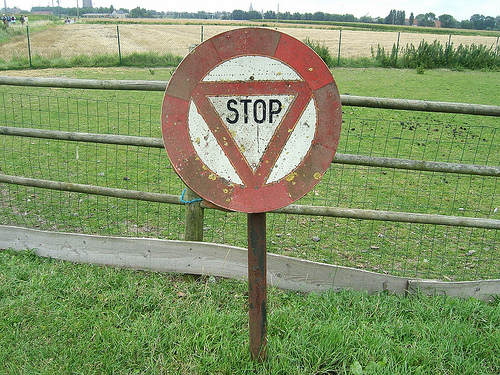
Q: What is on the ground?
A: Lush grass.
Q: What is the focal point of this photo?
A: A rusted stop sign.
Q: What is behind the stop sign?
A: A wire and wooden fence.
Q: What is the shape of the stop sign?
A: The signboard is circle.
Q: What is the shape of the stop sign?
A: The signboard is circle.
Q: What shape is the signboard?
A: Circle.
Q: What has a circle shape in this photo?
A: The signboard.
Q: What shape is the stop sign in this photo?
A: Circle.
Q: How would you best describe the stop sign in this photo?
A: Circle.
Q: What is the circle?
A: Red and white signboard.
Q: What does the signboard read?
A: Stop.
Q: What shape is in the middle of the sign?
A: Triangle.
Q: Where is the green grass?
A: Under the fence.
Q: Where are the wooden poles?
A: Along the fence.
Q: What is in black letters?
A: Stop.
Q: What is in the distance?
A: A field.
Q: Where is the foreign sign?
A: In front of fence,.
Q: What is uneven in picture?
A: Wood fence.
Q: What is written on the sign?
A: STOP.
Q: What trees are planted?
A: Cypress.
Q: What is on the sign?
A: Writing.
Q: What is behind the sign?
A: Fence.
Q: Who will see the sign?
A: People.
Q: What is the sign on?
A: Pole.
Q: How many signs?
A: 1.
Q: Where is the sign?
A: The ground.